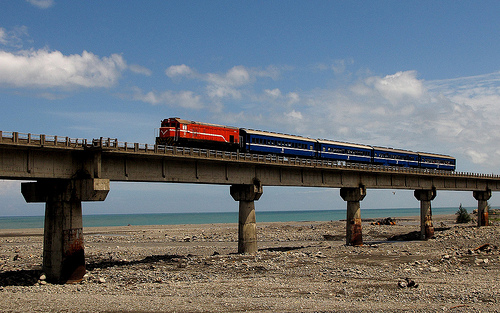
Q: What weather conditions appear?
A: It is cloudy.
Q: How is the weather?
A: It is cloudy.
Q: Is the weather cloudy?
A: Yes, it is cloudy.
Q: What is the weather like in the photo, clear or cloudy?
A: It is cloudy.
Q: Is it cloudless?
A: No, it is cloudy.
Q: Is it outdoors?
A: Yes, it is outdoors.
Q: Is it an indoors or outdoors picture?
A: It is outdoors.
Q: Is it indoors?
A: No, it is outdoors.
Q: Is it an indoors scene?
A: No, it is outdoors.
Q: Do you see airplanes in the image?
A: No, there are no airplanes.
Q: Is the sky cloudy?
A: Yes, the sky is cloudy.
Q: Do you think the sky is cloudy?
A: Yes, the sky is cloudy.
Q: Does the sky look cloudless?
A: No, the sky is cloudy.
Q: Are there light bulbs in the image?
A: No, there are no light bulbs.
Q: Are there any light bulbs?
A: No, there are no light bulbs.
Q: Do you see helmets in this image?
A: No, there are no helmets.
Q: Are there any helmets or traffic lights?
A: No, there are no helmets or traffic lights.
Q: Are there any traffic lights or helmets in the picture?
A: No, there are no helmets or traffic lights.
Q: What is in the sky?
A: The clouds are in the sky.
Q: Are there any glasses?
A: No, there are no glasses.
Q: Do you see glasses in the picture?
A: No, there are no glasses.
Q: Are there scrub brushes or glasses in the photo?
A: No, there are no glasses or scrub brushes.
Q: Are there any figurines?
A: No, there are no figurines.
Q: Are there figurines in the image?
A: No, there are no figurines.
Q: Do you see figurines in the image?
A: No, there are no figurines.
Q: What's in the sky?
A: The clouds are in the sky.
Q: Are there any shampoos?
A: No, there are no shampoos.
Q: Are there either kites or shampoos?
A: No, there are no shampoos or kites.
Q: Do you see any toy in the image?
A: No, there are no toys.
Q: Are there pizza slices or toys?
A: No, there are no toys or pizza slices.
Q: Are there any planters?
A: No, there are no planters.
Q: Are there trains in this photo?
A: Yes, there is a train.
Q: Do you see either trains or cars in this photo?
A: Yes, there is a train.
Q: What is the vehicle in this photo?
A: The vehicle is a train.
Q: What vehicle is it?
A: The vehicle is a train.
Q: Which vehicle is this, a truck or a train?
A: That is a train.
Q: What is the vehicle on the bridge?
A: The vehicle is a train.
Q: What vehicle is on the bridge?
A: The vehicle is a train.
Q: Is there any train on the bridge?
A: Yes, there is a train on the bridge.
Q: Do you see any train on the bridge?
A: Yes, there is a train on the bridge.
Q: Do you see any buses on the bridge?
A: No, there is a train on the bridge.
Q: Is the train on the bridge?
A: Yes, the train is on the bridge.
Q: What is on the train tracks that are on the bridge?
A: The train is on the railroad tracks.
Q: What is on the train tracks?
A: The train is on the railroad tracks.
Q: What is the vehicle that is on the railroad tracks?
A: The vehicle is a train.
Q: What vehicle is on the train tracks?
A: The vehicle is a train.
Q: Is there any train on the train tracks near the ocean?
A: Yes, there is a train on the tracks.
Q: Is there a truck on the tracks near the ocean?
A: No, there is a train on the tracks.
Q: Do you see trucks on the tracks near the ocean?
A: No, there is a train on the tracks.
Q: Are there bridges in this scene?
A: Yes, there is a bridge.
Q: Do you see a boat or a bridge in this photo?
A: Yes, there is a bridge.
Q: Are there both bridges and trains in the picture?
A: Yes, there are both a bridge and a train.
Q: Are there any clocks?
A: No, there are no clocks.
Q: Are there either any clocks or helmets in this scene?
A: No, there are no clocks or helmets.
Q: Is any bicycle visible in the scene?
A: No, there are no bicycles.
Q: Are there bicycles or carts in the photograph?
A: No, there are no bicycles or carts.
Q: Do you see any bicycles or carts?
A: No, there are no bicycles or carts.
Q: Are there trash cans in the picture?
A: No, there are no trash cans.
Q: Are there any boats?
A: No, there are no boats.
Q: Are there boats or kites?
A: No, there are no boats or kites.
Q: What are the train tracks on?
A: The train tracks are on the bridge.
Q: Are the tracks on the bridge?
A: Yes, the tracks are on the bridge.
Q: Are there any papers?
A: No, there are no papers.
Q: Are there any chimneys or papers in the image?
A: No, there are no papers or chimneys.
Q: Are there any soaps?
A: No, there are no soaps.